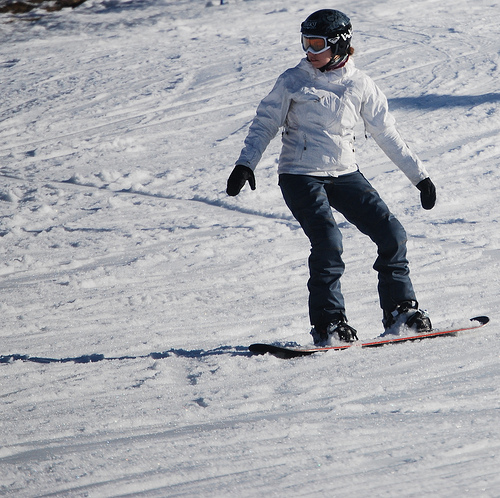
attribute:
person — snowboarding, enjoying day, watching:
[177, 6, 496, 392]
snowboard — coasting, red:
[241, 278, 498, 363]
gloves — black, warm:
[217, 149, 268, 194]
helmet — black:
[301, 6, 359, 49]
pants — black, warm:
[272, 165, 420, 320]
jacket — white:
[250, 55, 427, 187]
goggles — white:
[299, 30, 326, 55]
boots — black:
[305, 305, 358, 341]